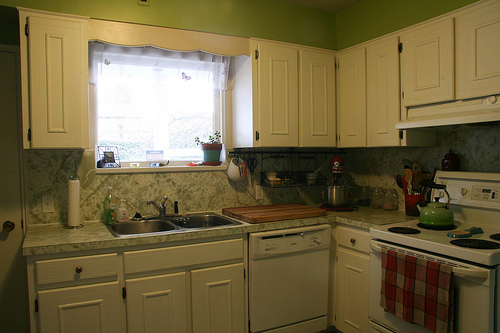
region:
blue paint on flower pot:
[207, 152, 218, 160]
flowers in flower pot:
[203, 133, 223, 142]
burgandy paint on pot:
[206, 144, 221, 151]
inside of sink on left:
[136, 224, 150, 230]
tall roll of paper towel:
[66, 181, 80, 227]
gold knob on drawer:
[70, 264, 88, 276]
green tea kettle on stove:
[415, 195, 456, 230]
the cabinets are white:
[237, 35, 489, 157]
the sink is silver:
[102, 202, 234, 237]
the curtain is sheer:
[96, 48, 226, 169]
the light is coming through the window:
[64, 59, 237, 179]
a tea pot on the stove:
[390, 165, 459, 232]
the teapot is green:
[375, 164, 466, 242]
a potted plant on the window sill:
[172, 120, 232, 171]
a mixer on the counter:
[312, 148, 361, 215]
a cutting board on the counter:
[206, 185, 336, 227]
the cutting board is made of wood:
[220, 187, 332, 235]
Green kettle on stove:
[416, 182, 456, 228]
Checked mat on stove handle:
[376, 250, 461, 331]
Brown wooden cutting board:
[225, 201, 326, 222]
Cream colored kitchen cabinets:
[41, 228, 339, 331]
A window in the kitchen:
[98, 41, 235, 166]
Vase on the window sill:
[198, 138, 221, 159]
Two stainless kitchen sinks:
[106, 212, 243, 242]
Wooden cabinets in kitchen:
[231, 5, 497, 161]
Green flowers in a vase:
[196, 130, 223, 166]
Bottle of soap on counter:
[103, 187, 116, 224]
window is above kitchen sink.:
[93, 46, 228, 171]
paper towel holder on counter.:
[61, 171, 81, 226]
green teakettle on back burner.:
[415, 180, 450, 225]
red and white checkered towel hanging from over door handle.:
[375, 245, 450, 330]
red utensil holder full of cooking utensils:
[390, 160, 425, 210]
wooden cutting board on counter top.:
[220, 200, 330, 220]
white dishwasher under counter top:
[250, 228, 330, 328]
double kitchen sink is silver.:
[100, 200, 240, 230]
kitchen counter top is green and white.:
[20, 218, 115, 249]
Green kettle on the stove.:
[414, 182, 454, 229]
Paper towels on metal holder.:
[56, 173, 89, 229]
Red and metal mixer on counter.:
[321, 153, 357, 210]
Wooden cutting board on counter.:
[221, 199, 331, 223]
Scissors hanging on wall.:
[247, 155, 259, 186]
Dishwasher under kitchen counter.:
[246, 223, 342, 328]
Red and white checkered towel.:
[378, 238, 459, 331]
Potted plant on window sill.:
[192, 131, 224, 166]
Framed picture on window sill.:
[95, 144, 121, 169]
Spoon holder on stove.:
[443, 225, 483, 237]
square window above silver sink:
[93, 51, 244, 240]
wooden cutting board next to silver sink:
[104, 196, 326, 238]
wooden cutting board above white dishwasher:
[220, 203, 332, 332]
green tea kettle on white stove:
[368, 166, 498, 332]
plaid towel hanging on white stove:
[364, 170, 499, 330]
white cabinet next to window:
[16, 8, 226, 170]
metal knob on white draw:
[33, 251, 119, 286]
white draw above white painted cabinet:
[33, 251, 128, 331]